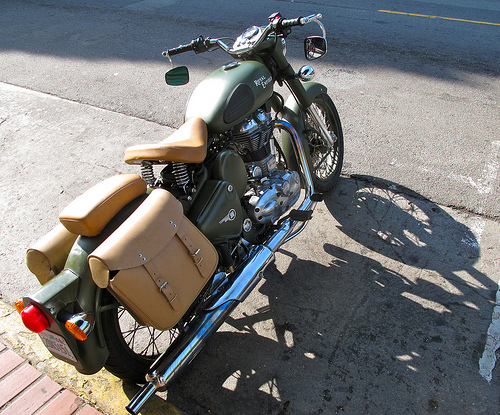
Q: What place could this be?
A: It is a road.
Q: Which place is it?
A: It is a road.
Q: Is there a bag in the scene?
A: Yes, there is a bag.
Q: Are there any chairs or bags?
A: Yes, there is a bag.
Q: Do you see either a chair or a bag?
A: Yes, there is a bag.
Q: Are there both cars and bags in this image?
A: No, there is a bag but no cars.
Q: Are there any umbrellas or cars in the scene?
A: No, there are no cars or umbrellas.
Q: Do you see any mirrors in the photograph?
A: Yes, there is a mirror.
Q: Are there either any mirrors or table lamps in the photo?
A: Yes, there is a mirror.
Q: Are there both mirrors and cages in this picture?
A: No, there is a mirror but no cages.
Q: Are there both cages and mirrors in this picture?
A: No, there is a mirror but no cages.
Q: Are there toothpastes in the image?
A: No, there are no toothpastes.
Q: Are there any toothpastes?
A: No, there are no toothpastes.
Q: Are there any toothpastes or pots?
A: No, there are no toothpastes or pots.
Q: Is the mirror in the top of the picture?
A: Yes, the mirror is in the top of the image.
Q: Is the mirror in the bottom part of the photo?
A: No, the mirror is in the top of the image.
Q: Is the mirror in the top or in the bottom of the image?
A: The mirror is in the top of the image.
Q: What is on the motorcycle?
A: The mirror is on the motorcycle.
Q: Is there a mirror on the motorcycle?
A: Yes, there is a mirror on the motorcycle.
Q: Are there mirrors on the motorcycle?
A: Yes, there is a mirror on the motorcycle.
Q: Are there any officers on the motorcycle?
A: No, there is a mirror on the motorcycle.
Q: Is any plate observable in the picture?
A: Yes, there is a plate.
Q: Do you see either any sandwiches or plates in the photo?
A: Yes, there is a plate.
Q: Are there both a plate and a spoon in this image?
A: No, there is a plate but no spoons.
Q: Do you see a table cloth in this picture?
A: No, there are no tablecloths.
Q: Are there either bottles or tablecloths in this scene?
A: No, there are no tablecloths or bottles.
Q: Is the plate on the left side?
A: Yes, the plate is on the left of the image.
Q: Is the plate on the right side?
A: No, the plate is on the left of the image.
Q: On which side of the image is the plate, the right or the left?
A: The plate is on the left of the image.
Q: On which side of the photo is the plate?
A: The plate is on the left of the image.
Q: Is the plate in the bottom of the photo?
A: Yes, the plate is in the bottom of the image.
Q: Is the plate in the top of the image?
A: No, the plate is in the bottom of the image.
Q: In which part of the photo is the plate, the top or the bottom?
A: The plate is in the bottom of the image.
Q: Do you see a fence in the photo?
A: No, there are no fences.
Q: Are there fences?
A: No, there are no fences.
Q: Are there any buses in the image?
A: No, there are no buses.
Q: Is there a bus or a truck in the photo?
A: No, there are no buses or trucks.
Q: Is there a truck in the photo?
A: No, there are no trucks.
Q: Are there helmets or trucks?
A: No, there are no trucks or helmets.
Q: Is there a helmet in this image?
A: No, there are no helmets.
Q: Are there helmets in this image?
A: No, there are no helmets.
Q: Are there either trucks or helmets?
A: No, there are no helmets or trucks.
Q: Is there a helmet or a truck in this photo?
A: No, there are no helmets or trucks.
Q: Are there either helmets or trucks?
A: No, there are no helmets or trucks.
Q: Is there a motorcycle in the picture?
A: Yes, there is a motorcycle.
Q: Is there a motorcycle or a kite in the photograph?
A: Yes, there is a motorcycle.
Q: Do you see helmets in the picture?
A: No, there are no helmets.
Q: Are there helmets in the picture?
A: No, there are no helmets.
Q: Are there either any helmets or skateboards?
A: No, there are no helmets or skateboards.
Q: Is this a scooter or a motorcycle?
A: This is a motorcycle.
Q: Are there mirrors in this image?
A: Yes, there is a mirror.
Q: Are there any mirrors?
A: Yes, there is a mirror.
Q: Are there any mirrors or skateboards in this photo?
A: Yes, there is a mirror.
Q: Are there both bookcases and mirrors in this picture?
A: No, there is a mirror but no bookcases.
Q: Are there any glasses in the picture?
A: No, there are no glasses.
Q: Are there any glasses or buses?
A: No, there are no glasses or buses.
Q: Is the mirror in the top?
A: Yes, the mirror is in the top of the image.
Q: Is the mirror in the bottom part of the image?
A: No, the mirror is in the top of the image.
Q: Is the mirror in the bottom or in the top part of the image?
A: The mirror is in the top of the image.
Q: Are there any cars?
A: No, there are no cars.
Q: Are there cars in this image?
A: No, there are no cars.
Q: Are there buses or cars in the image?
A: No, there are no cars or buses.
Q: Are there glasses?
A: No, there are no glasses.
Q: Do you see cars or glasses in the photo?
A: No, there are no glasses or cars.